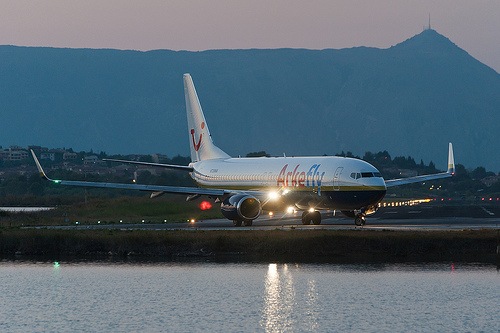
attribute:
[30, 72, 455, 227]
plane — large, red white, blue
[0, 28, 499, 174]
mountain — in the distance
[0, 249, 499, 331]
water — grey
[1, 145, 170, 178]
area — urban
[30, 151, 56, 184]
wing tips — upwards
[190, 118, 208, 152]
logo — red